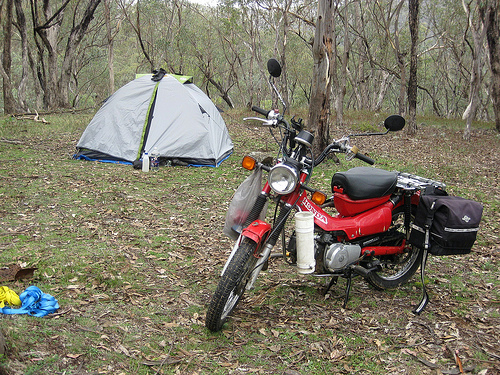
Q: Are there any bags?
A: Yes, there is a bag.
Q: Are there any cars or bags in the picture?
A: Yes, there is a bag.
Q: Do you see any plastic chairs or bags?
A: Yes, there is a plastic bag.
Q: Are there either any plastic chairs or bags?
A: Yes, there is a plastic bag.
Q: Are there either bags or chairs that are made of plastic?
A: Yes, the bag is made of plastic.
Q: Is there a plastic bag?
A: Yes, there is a bag that is made of plastic.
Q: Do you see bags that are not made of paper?
A: Yes, there is a bag that is made of plastic.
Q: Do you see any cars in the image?
A: No, there are no cars.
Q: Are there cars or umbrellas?
A: No, there are no cars or umbrellas.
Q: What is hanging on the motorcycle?
A: The bag is hanging on the motorbike.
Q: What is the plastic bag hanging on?
A: The bag is hanging on the motorbike.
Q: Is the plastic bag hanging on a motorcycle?
A: Yes, the bag is hanging on a motorcycle.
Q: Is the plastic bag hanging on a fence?
A: No, the bag is hanging on a motorcycle.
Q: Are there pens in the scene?
A: No, there are no pens.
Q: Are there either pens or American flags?
A: No, there are no pens or American flags.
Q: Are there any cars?
A: No, there are no cars.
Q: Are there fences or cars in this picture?
A: No, there are no cars or fences.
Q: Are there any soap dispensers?
A: No, there are no soap dispensers.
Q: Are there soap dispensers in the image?
A: No, there are no soap dispensers.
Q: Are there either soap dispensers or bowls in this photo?
A: No, there are no soap dispensers or bowls.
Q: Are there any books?
A: No, there are no books.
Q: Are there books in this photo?
A: No, there are no books.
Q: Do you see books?
A: No, there are no books.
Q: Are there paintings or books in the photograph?
A: No, there are no books or paintings.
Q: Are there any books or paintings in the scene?
A: No, there are no books or paintings.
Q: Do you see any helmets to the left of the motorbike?
A: No, there is a tent to the left of the motorbike.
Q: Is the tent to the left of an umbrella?
A: No, the tent is to the left of a motorcycle.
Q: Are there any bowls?
A: No, there are no bowls.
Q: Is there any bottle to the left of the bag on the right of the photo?
A: Yes, there are bottles to the left of the bag.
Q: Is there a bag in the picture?
A: Yes, there is a bag.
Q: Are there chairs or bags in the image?
A: Yes, there is a bag.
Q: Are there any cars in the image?
A: No, there are no cars.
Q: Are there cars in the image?
A: No, there are no cars.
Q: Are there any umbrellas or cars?
A: No, there are no cars or umbrellas.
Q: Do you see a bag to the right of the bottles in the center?
A: Yes, there is a bag to the right of the bottles.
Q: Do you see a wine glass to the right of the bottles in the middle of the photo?
A: No, there is a bag to the right of the bottles.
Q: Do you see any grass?
A: Yes, there is grass.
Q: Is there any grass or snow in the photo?
A: Yes, there is grass.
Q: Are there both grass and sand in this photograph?
A: No, there is grass but no sand.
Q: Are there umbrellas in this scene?
A: No, there are no umbrellas.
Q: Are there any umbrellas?
A: No, there are no umbrellas.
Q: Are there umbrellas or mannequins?
A: No, there are no umbrellas or mannequins.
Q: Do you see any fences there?
A: No, there are no fences.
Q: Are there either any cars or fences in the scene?
A: No, there are no fences or cars.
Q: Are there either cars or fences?
A: No, there are no cars or fences.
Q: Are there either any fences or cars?
A: No, there are no cars or fences.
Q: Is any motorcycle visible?
A: Yes, there is a motorcycle.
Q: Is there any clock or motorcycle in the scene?
A: Yes, there is a motorcycle.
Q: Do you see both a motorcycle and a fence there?
A: No, there is a motorcycle but no fences.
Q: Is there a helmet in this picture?
A: No, there are no helmets.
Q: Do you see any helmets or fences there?
A: No, there are no helmets or fences.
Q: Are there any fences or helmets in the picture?
A: No, there are no helmets or fences.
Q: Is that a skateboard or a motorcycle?
A: That is a motorcycle.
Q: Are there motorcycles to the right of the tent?
A: Yes, there is a motorcycle to the right of the tent.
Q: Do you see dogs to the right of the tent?
A: No, there is a motorcycle to the right of the tent.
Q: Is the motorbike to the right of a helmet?
A: No, the motorbike is to the right of a tent.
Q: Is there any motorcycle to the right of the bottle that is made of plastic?
A: Yes, there is a motorcycle to the right of the bottle.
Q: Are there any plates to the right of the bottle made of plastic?
A: No, there is a motorcycle to the right of the bottle.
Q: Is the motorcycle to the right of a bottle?
A: Yes, the motorcycle is to the right of a bottle.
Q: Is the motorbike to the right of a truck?
A: No, the motorbike is to the right of a bottle.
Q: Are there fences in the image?
A: No, there are no fences.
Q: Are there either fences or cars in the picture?
A: No, there are no fences or cars.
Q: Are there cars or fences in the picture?
A: No, there are no fences or cars.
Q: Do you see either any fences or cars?
A: No, there are no fences or cars.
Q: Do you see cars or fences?
A: No, there are no fences or cars.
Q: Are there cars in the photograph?
A: No, there are no cars.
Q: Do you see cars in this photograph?
A: No, there are no cars.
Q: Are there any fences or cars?
A: No, there are no cars or fences.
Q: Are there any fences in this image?
A: No, there are no fences.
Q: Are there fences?
A: No, there are no fences.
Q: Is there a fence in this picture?
A: No, there are no fences.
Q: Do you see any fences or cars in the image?
A: No, there are no fences or cars.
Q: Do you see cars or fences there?
A: No, there are no fences or cars.